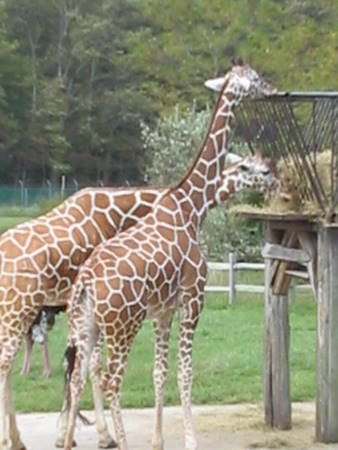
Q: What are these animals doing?
A: Eating grass.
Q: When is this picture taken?
A: Day time.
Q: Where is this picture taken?
A: Outside at the zoo.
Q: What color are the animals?
A: Brown and white.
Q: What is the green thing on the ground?
A: Grass.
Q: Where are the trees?
A: To the side of the animals.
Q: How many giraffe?
A: Two.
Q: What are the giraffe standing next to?
A: A ben.